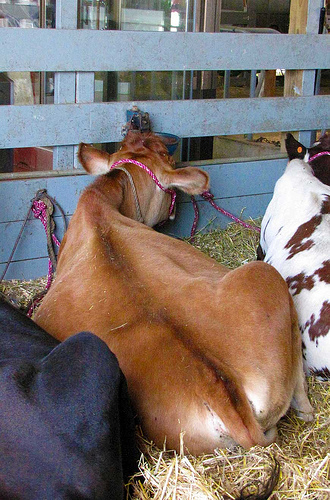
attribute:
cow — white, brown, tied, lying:
[245, 129, 329, 391]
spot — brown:
[282, 191, 328, 257]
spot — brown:
[278, 256, 329, 294]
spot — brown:
[295, 301, 329, 357]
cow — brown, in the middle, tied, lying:
[24, 123, 317, 468]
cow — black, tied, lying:
[0, 284, 142, 498]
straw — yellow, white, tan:
[0, 208, 327, 495]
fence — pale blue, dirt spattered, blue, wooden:
[3, 1, 328, 287]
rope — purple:
[105, 156, 181, 227]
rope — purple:
[298, 147, 329, 161]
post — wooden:
[283, 1, 324, 163]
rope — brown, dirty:
[114, 162, 148, 224]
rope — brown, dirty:
[40, 195, 63, 279]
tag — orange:
[294, 143, 304, 156]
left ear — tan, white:
[75, 136, 115, 175]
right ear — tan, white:
[165, 164, 212, 198]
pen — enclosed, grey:
[2, 5, 329, 500]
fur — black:
[2, 296, 136, 497]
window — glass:
[0, 2, 198, 170]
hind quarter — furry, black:
[37, 323, 147, 491]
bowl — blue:
[123, 107, 183, 162]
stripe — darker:
[96, 218, 258, 420]